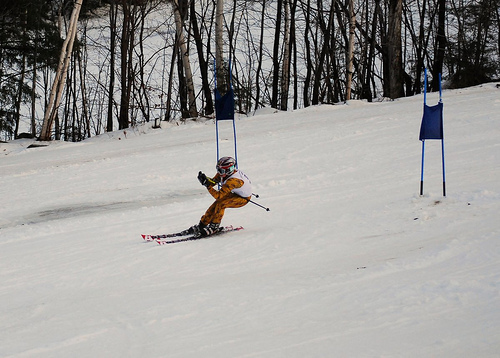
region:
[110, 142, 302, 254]
Downhill skier on the slope.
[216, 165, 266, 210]
White vest on the skier.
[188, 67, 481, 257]
Blue flags on the ski hill.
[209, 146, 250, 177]
Helmet on the skier's head.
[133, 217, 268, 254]
Skis on the person's feet.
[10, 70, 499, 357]
Ski hill.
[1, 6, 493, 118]
Trees in the background.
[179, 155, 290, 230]
Ski poles tucked under the skier's arms.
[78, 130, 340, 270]
One skier on the slope.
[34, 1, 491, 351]
Photo taken in the winter.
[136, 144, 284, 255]
Skater goes down the hill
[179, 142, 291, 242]
Skater has poles under arms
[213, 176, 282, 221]
Snow skaters are on back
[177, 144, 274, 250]
Skater wears a helmet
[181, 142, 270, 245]
Kid wears a white vest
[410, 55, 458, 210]
Blue sign in two poles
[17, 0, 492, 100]
Trunks of trees on top of hill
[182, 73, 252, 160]
Blue sign on the left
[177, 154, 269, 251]
Skater wears an orange snow suit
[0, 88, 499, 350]
Suit is cover with snow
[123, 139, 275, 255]
A downhill slalom skier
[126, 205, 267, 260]
A pair of snow skis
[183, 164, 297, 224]
A pair of skiing poles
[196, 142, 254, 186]
A downhill skiing helmet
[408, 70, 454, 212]
A slalom ski gate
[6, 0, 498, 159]
Trees in the background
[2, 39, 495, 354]
A snow-covered ski slope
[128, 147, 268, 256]
An orange and white ski suit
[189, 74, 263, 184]
A slalom ski gate behind a skier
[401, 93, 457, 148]
The flag on a slalom gate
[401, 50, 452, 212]
Wright signalization is blue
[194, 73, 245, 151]
Left sign is hold by two stick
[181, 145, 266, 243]
Skier is in motion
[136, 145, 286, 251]
Boy has two skies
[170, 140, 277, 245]
Boy wears a helmet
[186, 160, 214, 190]
Gloves are black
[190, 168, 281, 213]
Snow poles under arm of skier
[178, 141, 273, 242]
Boy wears a white vest of competition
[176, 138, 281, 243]
Skier has an orange winter suit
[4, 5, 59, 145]
Trees are green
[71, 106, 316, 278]
a person skiing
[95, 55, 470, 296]
a person racing down hill on skis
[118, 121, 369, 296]
the skier is wearing yellow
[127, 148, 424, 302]
a skier wearing a helmet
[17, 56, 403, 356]
a snowy landscape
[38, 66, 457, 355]
a skier going downhill on skis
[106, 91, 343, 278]
a person on skis is racing downhill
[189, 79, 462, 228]
the race markers are blue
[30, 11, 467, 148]
trees along side the ski trail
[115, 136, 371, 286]
a skier is holding ski poles